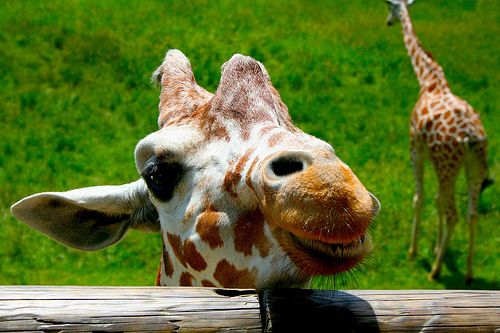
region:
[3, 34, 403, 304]
a giraffe leaning his head over a fence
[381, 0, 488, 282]
a giraffe turned with his back visible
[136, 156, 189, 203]
the eye of a giraffe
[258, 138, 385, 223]
the nose of a giraffe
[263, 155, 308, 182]
the nostril of a giraffe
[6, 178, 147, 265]
the ear of a giraffe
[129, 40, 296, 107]
the horns of a giraffe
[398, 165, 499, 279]
the legs of a giraffe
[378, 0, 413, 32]
the head of a giraffe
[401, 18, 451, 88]
the neck of a giraffe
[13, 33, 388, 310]
This is a giraffe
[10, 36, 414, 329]
This is a giraffe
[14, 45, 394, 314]
This is a giraffe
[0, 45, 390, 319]
This is a giraffe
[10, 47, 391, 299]
This is a giraffe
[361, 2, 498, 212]
This is a giraffe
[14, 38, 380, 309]
This is a giraffe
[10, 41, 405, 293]
This is a giraffe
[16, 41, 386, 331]
This is a giraffe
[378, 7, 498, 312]
This is a giraffe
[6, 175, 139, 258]
a young giraffe has an ear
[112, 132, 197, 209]
a giraffe has an eye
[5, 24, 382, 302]
a giraffe is on a wooden fence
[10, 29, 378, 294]
a white and brown giraffe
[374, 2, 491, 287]
a white and brown giraffe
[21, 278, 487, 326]
a long wooden fence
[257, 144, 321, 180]
a giraffe has a nostril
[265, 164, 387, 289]
the giraffe's mouth is open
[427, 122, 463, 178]
a giraffe has brown and white spots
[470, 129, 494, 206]
a giraffe has a tail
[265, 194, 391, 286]
the mouth of a giraffe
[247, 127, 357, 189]
the nose of a giraffe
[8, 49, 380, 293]
the head of a giraffe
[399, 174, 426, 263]
the leg of a giraffe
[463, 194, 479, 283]
the leg of a giraffe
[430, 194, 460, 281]
the legs of a giraffe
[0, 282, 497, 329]
a long wooden beam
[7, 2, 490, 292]
two giraffes on grass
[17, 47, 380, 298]
the giraffe is looking at the viewer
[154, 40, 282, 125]
the giraffe has small horns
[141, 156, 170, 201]
the giraffe has a black eye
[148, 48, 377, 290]
the giraffe has brown patches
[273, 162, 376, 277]
the giraffe has an orange brown mouth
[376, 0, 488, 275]
the giraffe is facing away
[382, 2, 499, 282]
the giraffe has a brown and white color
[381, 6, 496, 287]
the giraffe is standing still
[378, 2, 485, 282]
the giraffe is looking at the distance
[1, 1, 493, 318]
the field is filled with grass